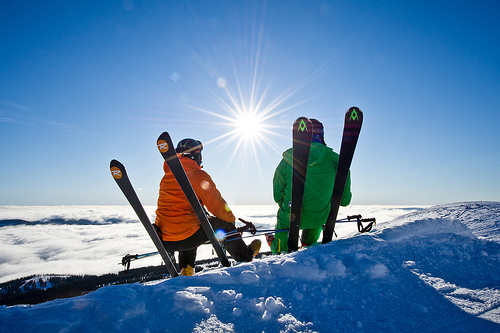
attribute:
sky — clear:
[350, 14, 433, 110]